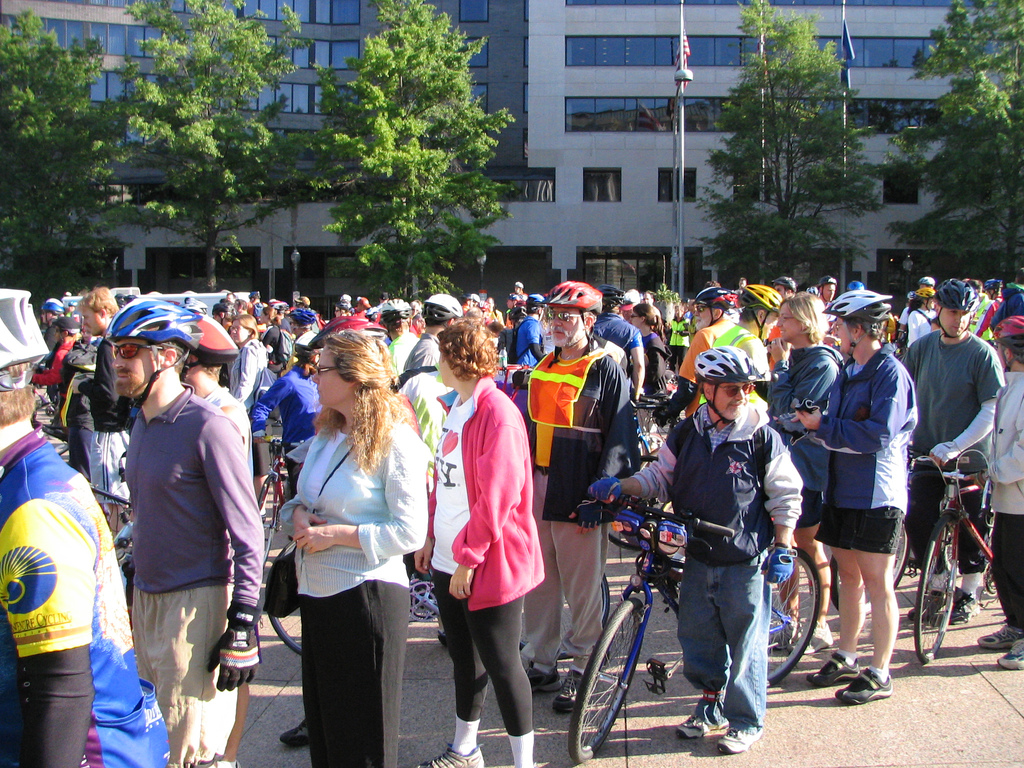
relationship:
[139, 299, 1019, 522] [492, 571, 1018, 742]
people standing on pavement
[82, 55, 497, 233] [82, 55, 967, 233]
trees in front of building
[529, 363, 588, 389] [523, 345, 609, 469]
stripe on vest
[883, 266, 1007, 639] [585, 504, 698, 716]
man standing next bike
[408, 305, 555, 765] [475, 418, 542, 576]
woman wearing coat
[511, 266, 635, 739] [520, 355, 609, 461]
man wearing vest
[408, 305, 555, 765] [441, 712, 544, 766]
woman wearing socks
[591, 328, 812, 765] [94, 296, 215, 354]
man wearing helmet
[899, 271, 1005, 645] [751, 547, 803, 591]
man wearing gloves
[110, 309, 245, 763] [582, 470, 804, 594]
man wearing gloves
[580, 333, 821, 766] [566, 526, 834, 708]
guy holding bicycle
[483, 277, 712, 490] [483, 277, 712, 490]
man has helmet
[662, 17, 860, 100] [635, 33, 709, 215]
flags on poles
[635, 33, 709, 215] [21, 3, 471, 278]
poles near trees